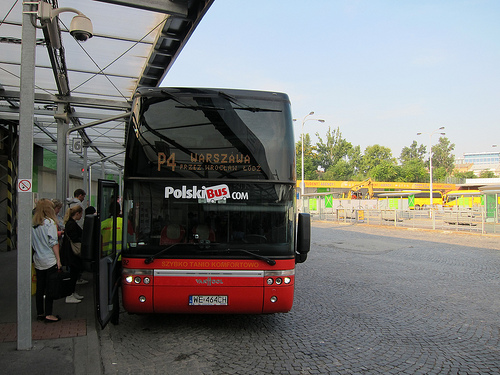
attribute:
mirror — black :
[297, 210, 318, 262]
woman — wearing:
[56, 200, 95, 295]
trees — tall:
[430, 136, 457, 172]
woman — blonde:
[56, 198, 83, 308]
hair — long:
[62, 200, 87, 224]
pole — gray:
[20, 3, 40, 351]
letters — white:
[221, 183, 253, 210]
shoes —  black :
[42, 313, 59, 324]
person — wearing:
[92, 199, 139, 326]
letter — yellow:
[185, 149, 257, 166]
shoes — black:
[28, 298, 76, 325]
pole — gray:
[5, 0, 38, 349]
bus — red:
[121, 87, 309, 311]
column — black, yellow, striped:
[0, 140, 23, 260]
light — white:
[35, 0, 93, 42]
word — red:
[204, 184, 231, 200]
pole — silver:
[14, 3, 40, 353]